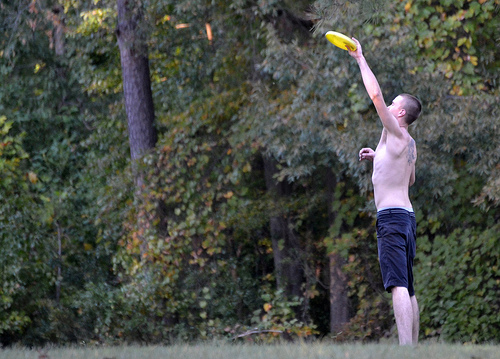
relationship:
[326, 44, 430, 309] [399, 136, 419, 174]
boy with tattoo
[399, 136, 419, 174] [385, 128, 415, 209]
tattoo on back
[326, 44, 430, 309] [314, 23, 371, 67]
boy holding frisbee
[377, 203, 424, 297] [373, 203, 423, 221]
shorts have belt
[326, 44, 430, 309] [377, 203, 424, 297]
boy wearing shorts